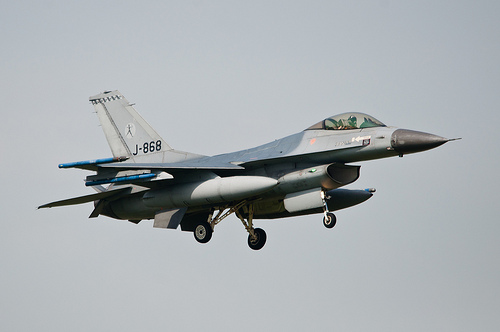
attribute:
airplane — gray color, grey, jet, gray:
[36, 89, 462, 250]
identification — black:
[132, 139, 163, 157]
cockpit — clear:
[308, 111, 388, 130]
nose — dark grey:
[388, 127, 463, 158]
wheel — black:
[193, 219, 213, 243]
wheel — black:
[248, 226, 268, 250]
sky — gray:
[1, 1, 499, 330]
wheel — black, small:
[322, 212, 337, 228]